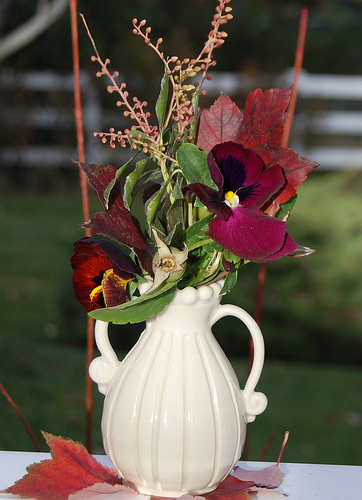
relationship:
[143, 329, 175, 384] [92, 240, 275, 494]
grooves in vase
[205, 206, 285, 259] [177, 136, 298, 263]
petal of flower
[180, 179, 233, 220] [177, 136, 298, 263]
petal of flower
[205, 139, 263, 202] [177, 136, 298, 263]
petal of flower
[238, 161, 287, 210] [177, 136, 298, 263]
petal of flower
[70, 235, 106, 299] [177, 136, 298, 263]
petals of flower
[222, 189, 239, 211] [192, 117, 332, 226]
center of flower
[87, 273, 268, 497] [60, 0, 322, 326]
vase holding flower arrangement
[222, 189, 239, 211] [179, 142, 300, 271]
center of a flower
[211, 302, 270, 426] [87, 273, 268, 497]
handle on a vase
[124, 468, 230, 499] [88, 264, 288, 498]
base on vase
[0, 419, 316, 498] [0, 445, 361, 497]
leaves on table top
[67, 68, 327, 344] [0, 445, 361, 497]
leaves on table top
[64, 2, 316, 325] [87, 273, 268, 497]
flowers in vase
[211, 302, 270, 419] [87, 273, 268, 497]
handle on vase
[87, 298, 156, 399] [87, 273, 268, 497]
handle on vase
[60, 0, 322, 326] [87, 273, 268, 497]
flower arrangement in vase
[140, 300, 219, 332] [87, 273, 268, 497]
short neck of vase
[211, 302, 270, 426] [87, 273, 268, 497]
handle on vase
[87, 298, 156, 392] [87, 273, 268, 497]
handle on vase